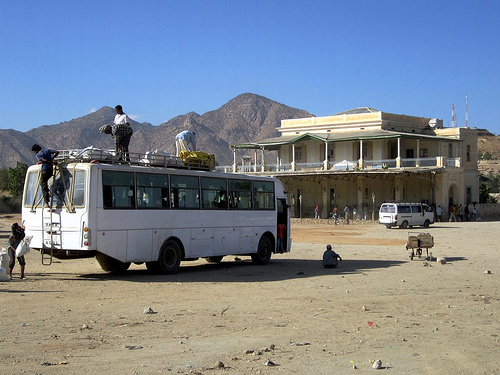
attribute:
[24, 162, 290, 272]
bus — white, large, passenger, here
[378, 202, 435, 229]
minivan — parked, here, white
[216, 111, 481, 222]
building — saloon, two story, here, tall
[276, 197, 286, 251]
door — open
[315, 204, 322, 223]
person — here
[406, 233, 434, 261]
buggy — shopping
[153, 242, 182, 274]
tire — black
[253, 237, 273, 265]
tire — black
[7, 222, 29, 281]
person — bending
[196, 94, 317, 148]
mountain — here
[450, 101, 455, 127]
tower — communications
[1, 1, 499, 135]
sky — blue